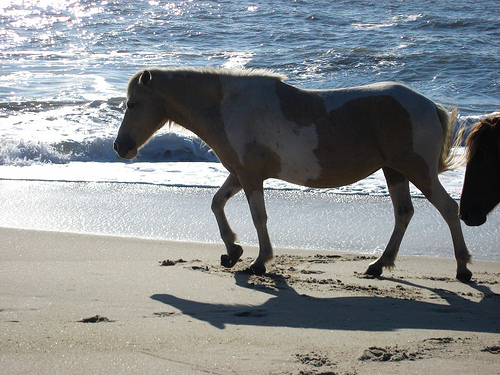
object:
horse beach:
[112, 66, 473, 305]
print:
[275, 254, 295, 264]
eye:
[123, 98, 138, 111]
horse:
[109, 66, 476, 284]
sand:
[61, 254, 128, 294]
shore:
[0, 172, 499, 373]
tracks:
[331, 277, 417, 299]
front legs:
[209, 176, 245, 269]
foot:
[221, 243, 244, 268]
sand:
[1, 319, 190, 373]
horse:
[459, 110, 499, 230]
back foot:
[363, 258, 393, 279]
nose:
[458, 207, 474, 222]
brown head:
[455, 112, 498, 230]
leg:
[235, 178, 275, 277]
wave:
[0, 94, 200, 171]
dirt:
[153, 281, 491, 351]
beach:
[0, 182, 500, 375]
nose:
[113, 137, 123, 153]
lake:
[0, 1, 499, 184]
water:
[0, 0, 500, 201]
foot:
[456, 262, 473, 282]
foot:
[245, 256, 268, 275]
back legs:
[363, 168, 414, 278]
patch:
[154, 144, 188, 162]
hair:
[152, 65, 289, 80]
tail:
[440, 106, 467, 174]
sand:
[385, 268, 492, 370]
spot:
[274, 75, 331, 127]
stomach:
[263, 158, 380, 190]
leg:
[411, 176, 472, 284]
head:
[111, 68, 171, 160]